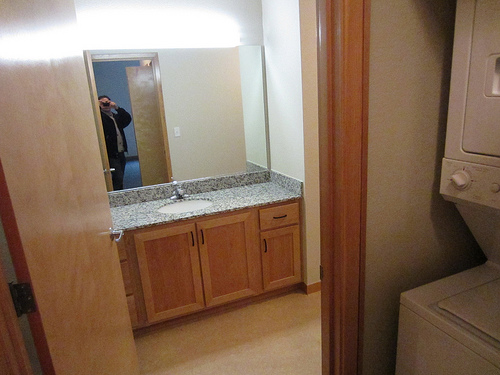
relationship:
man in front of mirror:
[94, 95, 139, 190] [85, 48, 177, 193]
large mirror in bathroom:
[88, 43, 268, 192] [74, 0, 324, 369]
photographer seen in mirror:
[95, 95, 135, 189] [91, 47, 269, 198]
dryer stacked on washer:
[438, 3, 498, 264] [393, 261, 498, 372]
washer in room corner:
[393, 261, 498, 372] [331, 4, 498, 373]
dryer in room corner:
[438, 3, 498, 264] [331, 4, 498, 373]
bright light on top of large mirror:
[74, 7, 262, 54] [83, 43, 273, 175]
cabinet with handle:
[136, 202, 301, 325] [184, 229, 197, 249]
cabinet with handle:
[197, 210, 261, 310] [195, 225, 206, 246]